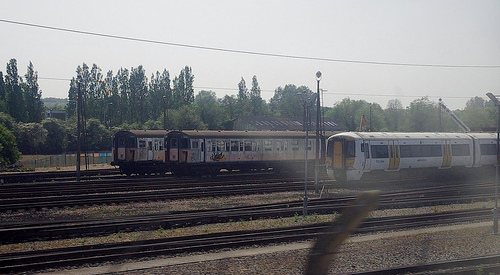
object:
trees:
[237, 80, 251, 120]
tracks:
[98, 203, 336, 222]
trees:
[48, 111, 69, 154]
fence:
[36, 84, 323, 164]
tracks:
[26, 174, 230, 185]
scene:
[29, 23, 447, 230]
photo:
[19, 10, 500, 275]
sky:
[395, 52, 495, 100]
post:
[309, 86, 342, 190]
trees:
[462, 84, 495, 127]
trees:
[191, 69, 220, 128]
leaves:
[95, 69, 102, 76]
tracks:
[27, 184, 322, 193]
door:
[357, 131, 373, 171]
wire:
[31, 25, 455, 68]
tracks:
[421, 260, 487, 271]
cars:
[118, 120, 165, 165]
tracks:
[107, 223, 462, 259]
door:
[386, 143, 400, 169]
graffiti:
[248, 151, 262, 160]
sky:
[25, 9, 355, 113]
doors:
[436, 137, 456, 169]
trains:
[326, 123, 500, 182]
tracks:
[3, 161, 115, 176]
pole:
[67, 71, 92, 190]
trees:
[411, 90, 441, 131]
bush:
[3, 124, 24, 164]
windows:
[479, 141, 500, 156]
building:
[235, 117, 354, 139]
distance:
[2, 31, 500, 202]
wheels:
[367, 176, 390, 183]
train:
[164, 128, 328, 179]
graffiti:
[201, 143, 229, 165]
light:
[75, 75, 83, 83]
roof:
[238, 117, 344, 131]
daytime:
[1, 3, 499, 268]